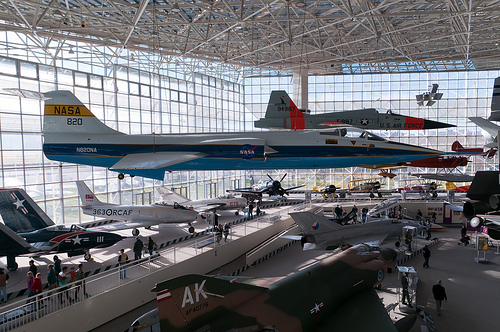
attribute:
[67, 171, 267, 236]
two planes — small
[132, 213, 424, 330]
plane — brown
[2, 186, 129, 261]
plane — small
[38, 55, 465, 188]
jet — white, blue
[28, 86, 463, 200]
plane — black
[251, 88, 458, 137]
jet — US, Air Force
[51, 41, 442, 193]
airplanes — various, types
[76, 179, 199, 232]
plane — small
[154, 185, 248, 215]
plane — small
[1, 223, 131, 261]
plane — small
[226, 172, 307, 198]
plane — small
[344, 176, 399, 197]
plane — small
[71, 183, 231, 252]
plane — white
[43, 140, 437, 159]
stripe — yellow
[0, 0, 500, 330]
showroom — airplane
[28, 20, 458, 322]
hangar — plane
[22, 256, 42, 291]
shirt — red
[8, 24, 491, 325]
museum — plane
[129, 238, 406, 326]
plane — old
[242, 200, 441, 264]
plane — old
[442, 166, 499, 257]
plane — old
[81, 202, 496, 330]
floor — museum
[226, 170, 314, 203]
plane — old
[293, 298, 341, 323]
logo — United States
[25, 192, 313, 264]
walkway — white